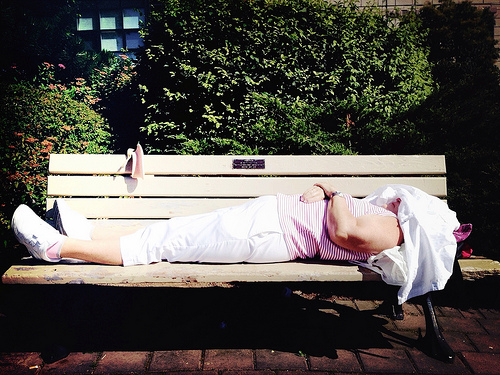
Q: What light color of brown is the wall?
A: Tan.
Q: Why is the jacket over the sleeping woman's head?
A: Block light.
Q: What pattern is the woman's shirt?
A: Striped.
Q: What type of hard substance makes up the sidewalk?
A: Bricks.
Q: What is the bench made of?
A: Wood.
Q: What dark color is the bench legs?
A: Black.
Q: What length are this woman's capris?
A: Calf length.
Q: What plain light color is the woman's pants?
A: White.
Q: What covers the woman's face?
A: Shirt.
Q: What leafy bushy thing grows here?
A: Bush.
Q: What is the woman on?
A: Bench.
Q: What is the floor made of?
A: Brick.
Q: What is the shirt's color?
A: Pink.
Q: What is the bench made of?
A: Wood.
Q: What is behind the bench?
A: Bushes.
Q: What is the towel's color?
A: White.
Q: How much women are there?
A: 1.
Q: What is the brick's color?
A: Red.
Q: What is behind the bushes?
A: Building.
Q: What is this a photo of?
A: A spot in the park.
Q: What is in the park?
A: A bench.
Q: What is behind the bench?
A: Bushes.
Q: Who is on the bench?
A: A lady.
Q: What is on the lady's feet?
A: Sneakers.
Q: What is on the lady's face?
A: A shirt.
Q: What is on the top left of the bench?
A: A flag.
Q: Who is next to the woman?
A: There is no one.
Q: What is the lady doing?
A: Laying down.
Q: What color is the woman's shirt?
A: Pink and white.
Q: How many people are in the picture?
A: One.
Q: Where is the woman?
A: On a bench.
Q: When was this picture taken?
A: During the day.